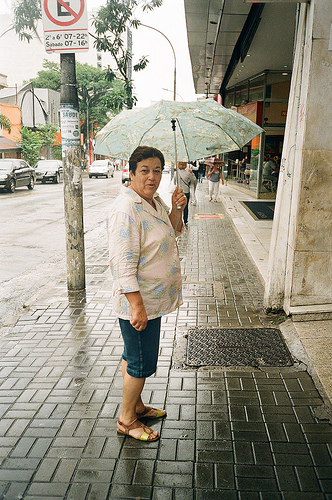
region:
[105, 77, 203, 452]
a woman holding an umbrella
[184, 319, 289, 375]
a man hole cover in the sidewalk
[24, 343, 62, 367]
brown bricks in the sidewalk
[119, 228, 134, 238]
a blue flower on blouse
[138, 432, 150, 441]
a yellow strap on a sandal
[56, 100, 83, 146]
a green and white flyer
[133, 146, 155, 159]
dark brown hair on a head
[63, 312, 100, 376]
a reflection on the wet sidewalk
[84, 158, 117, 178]
a white car driving on the street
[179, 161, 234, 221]
people walking on the sidewalk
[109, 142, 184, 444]
a woman in a pink shirt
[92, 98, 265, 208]
a blue umbrella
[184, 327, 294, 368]
a storm drain cover on the sidewalk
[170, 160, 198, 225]
a woman in a grey shirt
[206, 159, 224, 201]
a woman in a blue shirt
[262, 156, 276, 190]
a person sitting down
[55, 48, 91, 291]
a large wooden pole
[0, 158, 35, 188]
a black car on the road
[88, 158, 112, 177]
a white van on the road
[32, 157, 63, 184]
a black car on the road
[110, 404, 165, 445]
sandals on a person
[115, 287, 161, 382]
capri pants on a person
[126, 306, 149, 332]
a person's hand hanging down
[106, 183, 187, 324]
quarter length sleeve shirt on a person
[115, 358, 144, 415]
a person's calf muscles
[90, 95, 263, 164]
an unfurled umbrella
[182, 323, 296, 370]
a grate cover in a sidewalk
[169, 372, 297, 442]
a brick patterned sidewalk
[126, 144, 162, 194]
a person's face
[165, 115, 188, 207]
the stem of an umbrella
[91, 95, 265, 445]
A lady holding an umbrella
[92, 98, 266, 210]
A light blue and gold patterned umbrella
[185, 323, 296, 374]
A metal utility grate on the sidewalk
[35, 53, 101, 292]
A wooden pole on the sidewalk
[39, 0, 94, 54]
A red white and black sign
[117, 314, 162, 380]
Blue jean shorts the lady is wearing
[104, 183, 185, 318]
A white and blue flower patterned blouse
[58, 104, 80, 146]
a green and white sign attached to the wooden pole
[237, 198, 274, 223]
A black welcome mat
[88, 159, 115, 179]
A car driving down the street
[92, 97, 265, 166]
top of a woman's umbrella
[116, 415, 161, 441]
a woman's brown sandle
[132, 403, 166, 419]
a woman's brown sandle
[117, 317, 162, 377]
a woman's pair of shorts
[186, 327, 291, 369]
a metal grate in the sidewalk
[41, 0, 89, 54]
a white and red sign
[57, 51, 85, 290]
a thin wooden post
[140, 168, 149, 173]
eye of a woman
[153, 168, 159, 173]
eye of a woman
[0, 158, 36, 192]
a black car